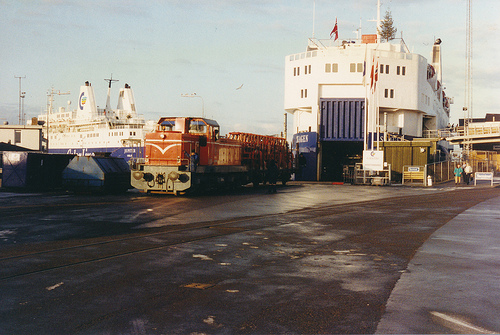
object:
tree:
[377, 7, 401, 42]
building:
[284, 50, 448, 186]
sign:
[362, 150, 384, 171]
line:
[66, 223, 406, 335]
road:
[1, 187, 500, 334]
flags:
[362, 48, 366, 87]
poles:
[376, 83, 379, 150]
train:
[126, 115, 294, 194]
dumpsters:
[61, 152, 130, 195]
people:
[453, 164, 463, 185]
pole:
[18, 78, 21, 125]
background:
[0, 0, 500, 335]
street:
[376, 190, 499, 333]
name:
[123, 149, 136, 158]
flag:
[329, 17, 339, 41]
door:
[316, 97, 371, 143]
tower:
[463, 0, 475, 187]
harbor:
[1, 0, 500, 335]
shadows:
[66, 166, 105, 194]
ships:
[280, 32, 469, 177]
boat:
[27, 73, 147, 168]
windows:
[325, 63, 332, 73]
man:
[464, 162, 473, 186]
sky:
[0, 0, 500, 131]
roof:
[281, 45, 443, 58]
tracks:
[0, 186, 500, 281]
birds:
[234, 84, 244, 92]